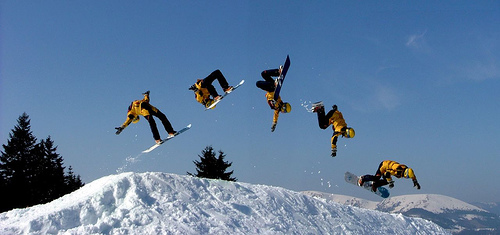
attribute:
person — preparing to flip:
[115, 87, 178, 144]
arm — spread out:
[118, 122, 133, 135]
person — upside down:
[255, 64, 292, 134]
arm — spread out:
[137, 84, 155, 104]